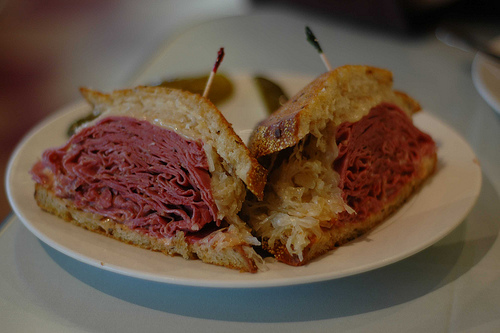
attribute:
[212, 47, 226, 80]
wrapper — red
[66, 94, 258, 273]
burger — half sliced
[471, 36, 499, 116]
plate — white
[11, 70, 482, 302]
round plate — white , round 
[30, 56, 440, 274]
sandwich — halved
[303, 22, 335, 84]
toothpick — green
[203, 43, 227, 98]
toothpick — red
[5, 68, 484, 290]
plate — white, round, ceramic 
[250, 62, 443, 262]
burger half — sliced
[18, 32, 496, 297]
plate — white 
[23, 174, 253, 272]
bread — bottom 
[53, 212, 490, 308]
shadow — Plate's 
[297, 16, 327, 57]
wrapper — Green 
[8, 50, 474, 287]
plate — round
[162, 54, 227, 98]
tooth pick — wooden